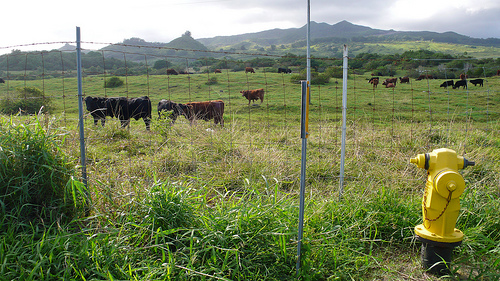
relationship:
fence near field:
[80, 36, 371, 222] [125, 60, 484, 129]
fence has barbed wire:
[80, 36, 371, 222] [58, 37, 492, 69]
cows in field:
[108, 69, 494, 121] [125, 60, 484, 129]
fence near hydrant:
[80, 36, 371, 222] [409, 142, 468, 249]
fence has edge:
[80, 36, 371, 222] [95, 25, 497, 128]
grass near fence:
[41, 134, 390, 278] [80, 36, 371, 222]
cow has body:
[235, 84, 264, 107] [250, 88, 269, 99]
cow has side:
[235, 84, 264, 107] [243, 86, 255, 105]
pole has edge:
[322, 49, 353, 196] [335, 50, 340, 195]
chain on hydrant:
[422, 185, 456, 219] [409, 142, 468, 249]